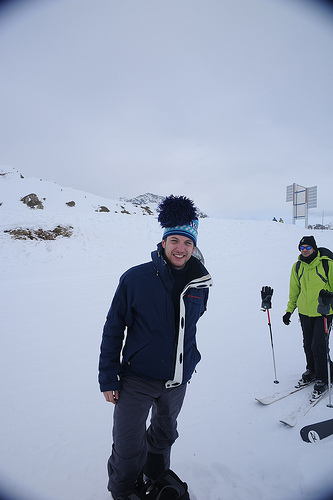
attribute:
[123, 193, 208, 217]
mountain — snowy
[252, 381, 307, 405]
ski — white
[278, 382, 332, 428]
ski — white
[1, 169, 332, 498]
snow — white, cold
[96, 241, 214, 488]
clothes — warm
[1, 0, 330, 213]
sky — gray, cloudy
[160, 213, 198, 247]
hat — blue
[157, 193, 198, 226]
topper — fluffy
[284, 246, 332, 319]
jacket — green, greenish yellow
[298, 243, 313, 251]
glasses — blue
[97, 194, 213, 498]
man — smiling, young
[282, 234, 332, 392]
man — elder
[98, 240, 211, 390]
ski jacket — navy blue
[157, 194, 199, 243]
cap — blue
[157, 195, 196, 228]
ball — black, fuzzy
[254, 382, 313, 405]
ski — white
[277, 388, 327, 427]
ski — white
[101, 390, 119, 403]
hand — bare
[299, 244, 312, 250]
sunglasses — blue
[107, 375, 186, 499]
sweatpants — gray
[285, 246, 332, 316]
sweater — green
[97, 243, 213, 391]
sweater — blue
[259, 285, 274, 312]
glove — black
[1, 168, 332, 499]
hill — snowy